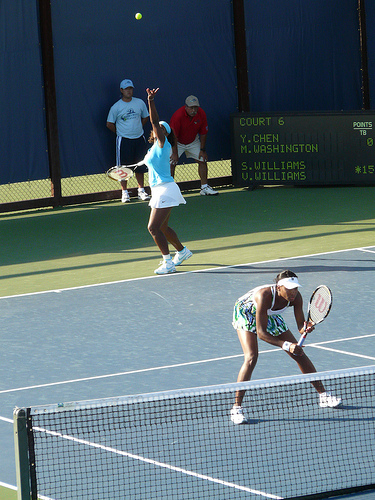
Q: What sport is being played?
A: Tennis.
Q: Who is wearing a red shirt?
A: The man.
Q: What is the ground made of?
A: Cement and paint.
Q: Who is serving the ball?
A: Woman in the back.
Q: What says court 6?
A: The sign in yellow.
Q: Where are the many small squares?
A: In the net.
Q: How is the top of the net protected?
A: With white plastic trim.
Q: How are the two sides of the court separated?
A: With a net.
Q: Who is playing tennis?
A: Two women.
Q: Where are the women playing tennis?
A: On a court.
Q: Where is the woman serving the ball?
A: Behind the white line.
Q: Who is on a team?
A: The two women.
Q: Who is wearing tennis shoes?
A: The people.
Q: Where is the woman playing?
A: On a tennis court.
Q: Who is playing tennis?
A: The two women.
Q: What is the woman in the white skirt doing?
A: Serving the tennis ball.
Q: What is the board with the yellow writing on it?
A: The scoreboard.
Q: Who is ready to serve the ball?
A: The woman.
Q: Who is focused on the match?
A: The two athletes.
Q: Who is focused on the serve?
A: The woman.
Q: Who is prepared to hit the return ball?
A: The tennis player in front.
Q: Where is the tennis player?
A: On a tennis court.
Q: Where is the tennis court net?
A: In front of the player.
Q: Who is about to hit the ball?
A: The tennis player.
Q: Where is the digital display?
A: On the tennis court.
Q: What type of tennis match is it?
A: Women's doubles.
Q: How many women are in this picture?
A: Two.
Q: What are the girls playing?
A: Tennis.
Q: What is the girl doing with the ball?
A: Serving.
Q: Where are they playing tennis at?
A: Tennis Court.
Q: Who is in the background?
A: Judges.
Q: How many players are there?
A: 4.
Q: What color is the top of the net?
A: White.